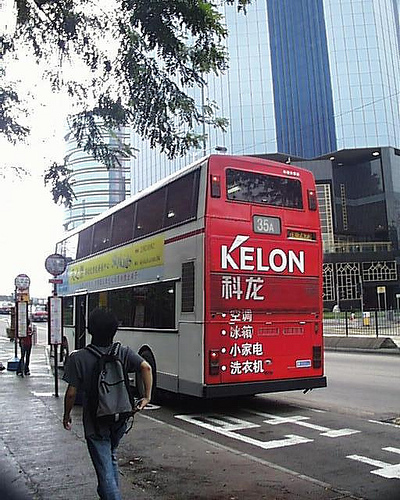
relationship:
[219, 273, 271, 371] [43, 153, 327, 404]
writing on bus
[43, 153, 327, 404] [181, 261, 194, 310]
bus has vent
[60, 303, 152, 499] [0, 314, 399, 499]
man walking along road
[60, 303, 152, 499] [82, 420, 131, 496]
man wearing jeans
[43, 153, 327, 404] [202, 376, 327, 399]
bus has bumper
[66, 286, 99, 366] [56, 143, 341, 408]
door on bus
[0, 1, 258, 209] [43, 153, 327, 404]
tree limb above bus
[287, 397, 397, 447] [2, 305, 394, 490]
white line on road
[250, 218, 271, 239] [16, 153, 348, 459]
number on bus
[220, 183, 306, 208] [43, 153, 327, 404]
windshield on bus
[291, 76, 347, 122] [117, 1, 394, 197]
windows on building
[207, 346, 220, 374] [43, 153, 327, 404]
light on bus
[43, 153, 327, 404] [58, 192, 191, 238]
bus has second story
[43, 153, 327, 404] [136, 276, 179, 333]
bus has window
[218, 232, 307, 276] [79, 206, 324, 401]
word on back of bus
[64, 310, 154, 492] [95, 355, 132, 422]
man has backpack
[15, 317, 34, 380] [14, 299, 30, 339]
someone behind sign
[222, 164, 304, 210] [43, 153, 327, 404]
back window of a bus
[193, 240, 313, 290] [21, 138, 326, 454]
name on bus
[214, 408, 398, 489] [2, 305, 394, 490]
street sign on road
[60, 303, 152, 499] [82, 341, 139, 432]
man walking with backpack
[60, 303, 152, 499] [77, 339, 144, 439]
man carrying backpack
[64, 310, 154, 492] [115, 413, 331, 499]
man on sidewalk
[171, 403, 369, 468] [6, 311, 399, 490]
lines on street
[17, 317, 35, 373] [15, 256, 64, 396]
someone at stop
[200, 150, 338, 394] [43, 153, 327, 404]
back of bus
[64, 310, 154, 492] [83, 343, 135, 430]
man wearing backpack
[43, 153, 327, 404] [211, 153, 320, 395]
bus has back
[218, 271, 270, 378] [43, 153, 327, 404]
foreign language written on bus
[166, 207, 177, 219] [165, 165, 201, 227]
light reflected in window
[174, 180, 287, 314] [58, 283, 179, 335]
bus has window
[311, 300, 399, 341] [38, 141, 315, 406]
fence behind bus